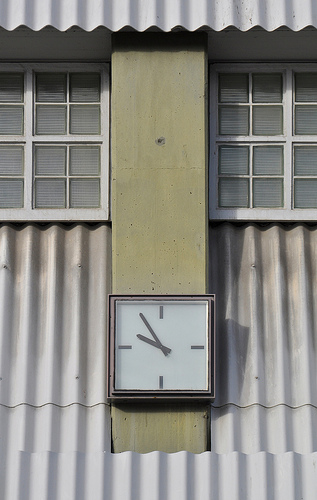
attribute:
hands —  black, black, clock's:
[135, 313, 170, 358]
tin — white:
[2, 225, 315, 486]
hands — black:
[134, 309, 171, 359]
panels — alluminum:
[215, 222, 314, 447]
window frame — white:
[207, 61, 316, 220]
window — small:
[1, 64, 109, 221]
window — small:
[209, 58, 315, 220]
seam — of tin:
[4, 399, 107, 411]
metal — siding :
[0, 221, 112, 405]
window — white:
[0, 53, 116, 237]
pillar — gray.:
[106, 50, 219, 296]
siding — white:
[3, 226, 312, 496]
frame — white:
[103, 290, 218, 402]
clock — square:
[107, 286, 228, 411]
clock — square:
[77, 308, 215, 404]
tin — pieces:
[0, 226, 110, 405]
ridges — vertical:
[42, 219, 65, 453]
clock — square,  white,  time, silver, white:
[105, 292, 216, 400]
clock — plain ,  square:
[106, 294, 211, 394]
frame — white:
[206, 60, 219, 217]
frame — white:
[92, 55, 110, 211]